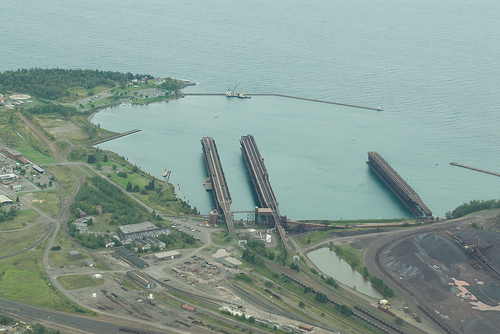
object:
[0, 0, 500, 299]
water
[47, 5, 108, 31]
clouds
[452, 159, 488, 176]
pier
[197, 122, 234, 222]
piers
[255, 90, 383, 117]
wall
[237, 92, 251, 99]
boat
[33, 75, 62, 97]
trees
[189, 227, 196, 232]
cars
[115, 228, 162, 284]
buildings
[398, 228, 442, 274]
pile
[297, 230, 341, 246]
grass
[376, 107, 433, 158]
opening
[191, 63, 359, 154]
area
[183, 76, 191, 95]
docking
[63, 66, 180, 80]
shore